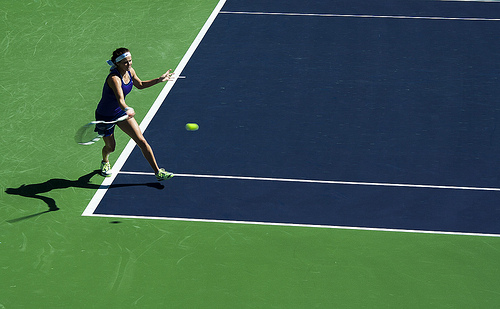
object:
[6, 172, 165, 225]
shadow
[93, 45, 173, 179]
player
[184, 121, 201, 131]
ball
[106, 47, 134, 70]
head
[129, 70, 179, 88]
arm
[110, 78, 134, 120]
arm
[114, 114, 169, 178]
leg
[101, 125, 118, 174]
leg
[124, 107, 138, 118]
hand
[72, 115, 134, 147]
racket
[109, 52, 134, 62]
band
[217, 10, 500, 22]
line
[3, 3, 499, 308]
court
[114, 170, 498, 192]
line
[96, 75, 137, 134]
outfit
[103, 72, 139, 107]
tank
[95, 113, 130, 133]
shorts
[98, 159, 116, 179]
shoes